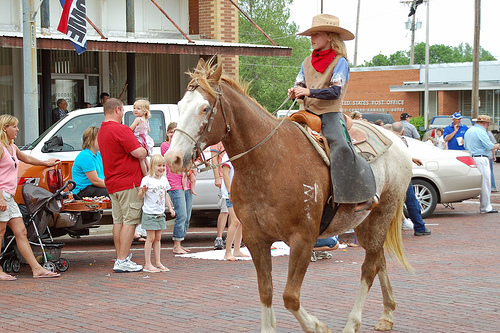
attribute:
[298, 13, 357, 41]
cowboy hat — tan, brown, beige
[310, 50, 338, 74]
bandana — red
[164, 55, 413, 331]
horse — brown, white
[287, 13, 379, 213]
girl — young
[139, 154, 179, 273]
young girl — standing, blond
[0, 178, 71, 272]
stroller — black, gray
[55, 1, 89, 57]
flag — hanging, red, blue, white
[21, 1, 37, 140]
pole — wood, wooden, long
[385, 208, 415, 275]
hair — blond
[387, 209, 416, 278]
horse tail — blond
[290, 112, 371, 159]
saddle — orange, brown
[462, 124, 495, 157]
shirt — blue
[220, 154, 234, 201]
shirt — brown, white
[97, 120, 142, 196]
shirt — red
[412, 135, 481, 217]
car — champagne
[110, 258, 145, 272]
tennis shoe — white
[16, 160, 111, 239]
car — orange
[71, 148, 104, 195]
top — blue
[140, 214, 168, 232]
skirt — green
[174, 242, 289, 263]
blanket — white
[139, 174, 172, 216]
shirt — white